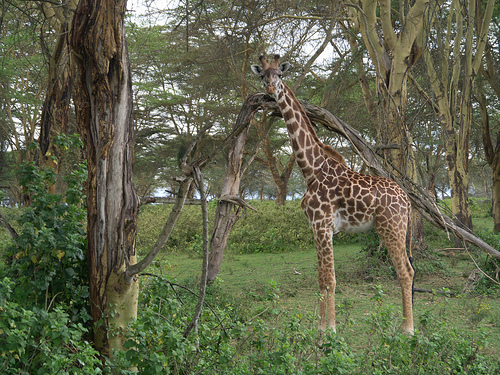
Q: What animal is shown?
A: Giraffe.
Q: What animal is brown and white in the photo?
A: Giraffe.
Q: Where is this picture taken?
A: A forest.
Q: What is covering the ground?
A: Grasses.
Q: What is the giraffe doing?
A: Standing.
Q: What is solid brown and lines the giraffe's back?
A: A mane.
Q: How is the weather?
A: Clear.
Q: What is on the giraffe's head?
A: Horns.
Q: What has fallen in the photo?
A: A tree.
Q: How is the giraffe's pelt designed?
A: In spots.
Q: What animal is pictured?
A: A giraffe.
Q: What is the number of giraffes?
A: One.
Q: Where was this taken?
A: A forest.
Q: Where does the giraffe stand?
A: Green grass.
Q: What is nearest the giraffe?
A: Fallen branches.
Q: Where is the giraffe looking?
A: Directly ahead.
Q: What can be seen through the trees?
A: Sky.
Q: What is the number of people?
A: Zero.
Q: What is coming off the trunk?
A: Bark.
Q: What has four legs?
A: Giraffe.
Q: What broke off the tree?
A: Branch.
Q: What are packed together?
A: Trees.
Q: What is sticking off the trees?
A: Branch.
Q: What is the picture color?
A: Brown, yellow and white.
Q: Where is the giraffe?
A: A forest.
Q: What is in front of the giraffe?
A: Bushes.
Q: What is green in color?
A: The forest.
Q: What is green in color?
A: The forest.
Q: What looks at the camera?
A: A giraffe.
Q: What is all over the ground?
A: Weeds.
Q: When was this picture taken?
A: During the day.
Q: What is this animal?
A: A giraffe.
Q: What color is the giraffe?
A: Tan and brown.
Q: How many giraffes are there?
A: 1.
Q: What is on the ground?
A: Grass.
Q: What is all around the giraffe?
A: Trees and shrubs.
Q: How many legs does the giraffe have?
A: 4.